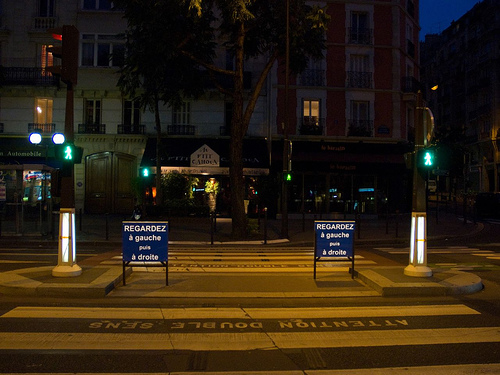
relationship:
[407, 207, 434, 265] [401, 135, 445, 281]
light in statue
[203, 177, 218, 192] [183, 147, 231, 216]
light inside of a statue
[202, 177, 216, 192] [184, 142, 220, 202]
light inside of a statue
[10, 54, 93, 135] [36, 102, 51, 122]
building has a window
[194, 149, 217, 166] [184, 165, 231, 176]
sign on awning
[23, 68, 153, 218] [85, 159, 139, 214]
building has a door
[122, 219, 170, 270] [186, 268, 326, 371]
sign on street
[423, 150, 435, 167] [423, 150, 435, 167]
human figure has a pedestrian human figure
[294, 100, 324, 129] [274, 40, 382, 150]
window on a building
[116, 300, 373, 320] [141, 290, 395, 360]
stripe painted on street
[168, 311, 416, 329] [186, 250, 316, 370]
words printed on street